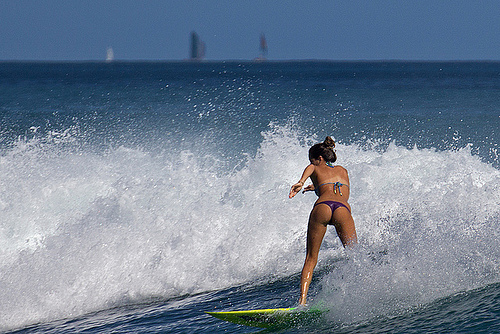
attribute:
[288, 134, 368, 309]
woman — surfing, riding, tan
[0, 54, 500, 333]
ocean — blue, green, white, very blue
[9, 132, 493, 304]
wave — crashing, large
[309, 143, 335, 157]
hair — bun, up, ponytail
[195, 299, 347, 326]
surfboard — yellow, green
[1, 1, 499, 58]
sky — blue, clear, gray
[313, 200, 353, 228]
bikini bottom — purple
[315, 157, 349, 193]
bikini top — blue, string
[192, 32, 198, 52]
sail — black